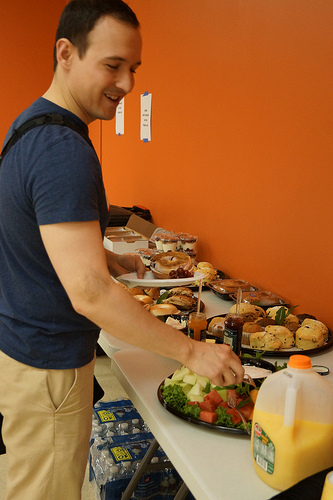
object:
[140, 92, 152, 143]
sign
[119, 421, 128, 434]
water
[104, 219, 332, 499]
table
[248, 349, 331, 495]
gallon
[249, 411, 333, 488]
juice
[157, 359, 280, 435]
tray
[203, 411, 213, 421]
fruit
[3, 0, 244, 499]
man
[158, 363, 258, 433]
food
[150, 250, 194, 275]
bagel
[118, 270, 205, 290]
plate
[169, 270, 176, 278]
grapes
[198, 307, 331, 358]
tray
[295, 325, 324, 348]
pastries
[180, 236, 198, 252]
parfaits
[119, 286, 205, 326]
tray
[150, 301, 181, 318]
bagels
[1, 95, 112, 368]
shirt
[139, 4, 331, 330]
wall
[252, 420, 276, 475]
sticker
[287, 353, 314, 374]
top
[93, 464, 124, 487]
packaging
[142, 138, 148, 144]
tape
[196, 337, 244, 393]
hand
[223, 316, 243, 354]
jar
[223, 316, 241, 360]
jam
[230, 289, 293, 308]
container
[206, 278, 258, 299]
container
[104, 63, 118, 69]
eyes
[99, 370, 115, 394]
floor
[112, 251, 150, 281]
hand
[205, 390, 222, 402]
watermelon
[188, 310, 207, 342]
jellie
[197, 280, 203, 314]
spoon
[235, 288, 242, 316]
spoon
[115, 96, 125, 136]
paper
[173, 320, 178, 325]
cream cheese